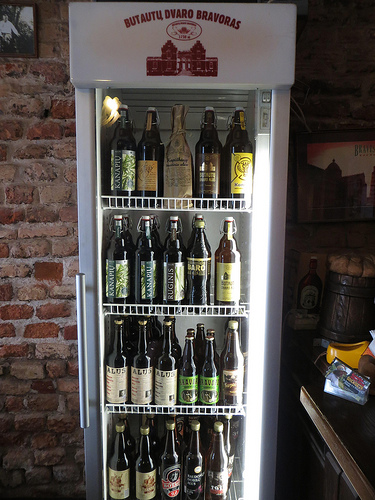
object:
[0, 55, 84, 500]
brick wall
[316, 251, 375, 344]
decoration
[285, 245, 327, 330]
box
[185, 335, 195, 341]
cap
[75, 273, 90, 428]
door handle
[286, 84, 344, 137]
ground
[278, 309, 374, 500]
wooden case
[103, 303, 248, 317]
shelf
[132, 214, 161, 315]
bottle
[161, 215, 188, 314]
bottle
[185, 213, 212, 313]
bottle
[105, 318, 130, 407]
bottle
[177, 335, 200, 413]
bottle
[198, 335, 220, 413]
bottle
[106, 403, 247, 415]
shelf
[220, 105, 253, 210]
beer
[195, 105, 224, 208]
beer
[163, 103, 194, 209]
beer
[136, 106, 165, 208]
beer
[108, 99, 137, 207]
beer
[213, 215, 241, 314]
beer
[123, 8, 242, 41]
red lettering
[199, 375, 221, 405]
label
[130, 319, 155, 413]
beer bottle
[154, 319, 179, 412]
bottle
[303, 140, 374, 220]
sign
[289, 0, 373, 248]
wall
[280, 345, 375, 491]
counter top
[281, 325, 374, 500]
counter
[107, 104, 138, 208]
beer bottle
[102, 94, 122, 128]
light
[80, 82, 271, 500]
door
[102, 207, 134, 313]
beer bottle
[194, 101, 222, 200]
bottle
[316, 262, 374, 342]
barrel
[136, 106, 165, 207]
bottle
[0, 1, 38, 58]
photo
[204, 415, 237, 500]
bottles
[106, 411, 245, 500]
bottom shelf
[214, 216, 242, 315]
beer bottle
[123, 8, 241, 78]
name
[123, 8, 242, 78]
advertisement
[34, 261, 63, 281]
red brick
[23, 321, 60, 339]
red brick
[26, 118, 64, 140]
red brick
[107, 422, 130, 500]
beer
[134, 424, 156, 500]
beer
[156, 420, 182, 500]
beer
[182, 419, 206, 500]
beer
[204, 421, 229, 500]
beer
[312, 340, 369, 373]
decor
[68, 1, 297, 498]
cooler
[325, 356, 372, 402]
cards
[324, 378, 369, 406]
container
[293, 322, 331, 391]
liqour